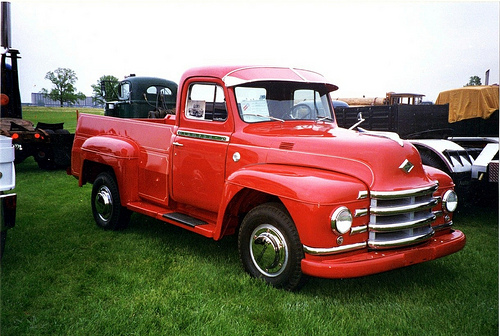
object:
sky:
[11, 0, 500, 103]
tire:
[237, 202, 307, 292]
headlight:
[330, 203, 355, 233]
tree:
[40, 67, 86, 107]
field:
[0, 105, 500, 336]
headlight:
[443, 189, 459, 211]